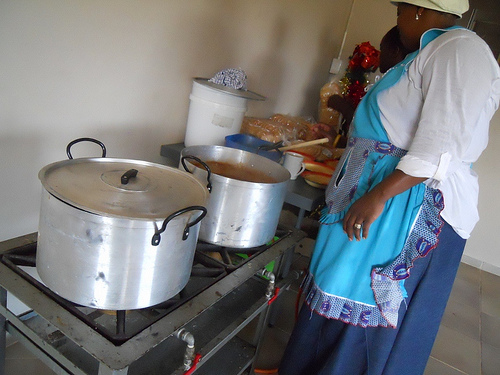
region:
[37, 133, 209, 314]
this is a cooking pot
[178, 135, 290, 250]
this is a cooking pot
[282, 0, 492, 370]
this is a person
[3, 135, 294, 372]
this is a stove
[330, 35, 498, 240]
this is a persons hand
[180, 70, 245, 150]
this is a bucket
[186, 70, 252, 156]
this is a white bucket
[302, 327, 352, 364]
this is blue in colour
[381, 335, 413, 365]
this is blue in colour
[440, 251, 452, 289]
this is blue in colour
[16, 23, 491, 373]
Two people cooking a large meal.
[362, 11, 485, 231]
Woman wearing a white shirt.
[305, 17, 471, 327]
Woman wearing an apron.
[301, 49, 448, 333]
A light blue apron with dark blue ruffle.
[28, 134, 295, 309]
Two large pots on stove.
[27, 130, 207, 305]
Large stainless steel pot with lid.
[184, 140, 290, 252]
Large stainless steel pot without lid.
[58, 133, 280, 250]
Both pots have black handles.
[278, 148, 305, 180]
A white coffee cup.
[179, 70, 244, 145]
A large white plastic bucket.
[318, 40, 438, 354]
the apron is blue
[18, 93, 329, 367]
two big pots on the stove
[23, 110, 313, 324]
two big pots on the stove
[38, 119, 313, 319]
two big pots on the stove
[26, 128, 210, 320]
Pot on the stove.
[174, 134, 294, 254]
Food cooking on the stove.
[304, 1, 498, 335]
Blue apron on the woman.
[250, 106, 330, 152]
food on the counter.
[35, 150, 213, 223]
Lid on the pot.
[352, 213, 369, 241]
Ring on the finger.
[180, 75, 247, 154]
White container on the counter.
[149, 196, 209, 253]
black handle on the pot.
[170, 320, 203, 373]
Gas line on the stove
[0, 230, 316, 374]
Stove in the room.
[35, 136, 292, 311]
two large pots of soup on gas stove burners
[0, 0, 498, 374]
black woman cooking on stand alone gas two burner stove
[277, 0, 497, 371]
woman in blue skirt, light blue apron, and white shirt and whit hat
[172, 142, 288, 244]
large aluminum stock pot on gas range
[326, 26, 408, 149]
black woman working in kitchen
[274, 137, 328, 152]
wooden cooking utensil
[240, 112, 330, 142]
breads in plastic wrappers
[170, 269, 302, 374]
metal gas supply pipes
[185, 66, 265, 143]
white plastic 5 gallon bucket covered with metal lid and kitchen towel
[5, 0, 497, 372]
two black women cooking in a very minimal kitchen